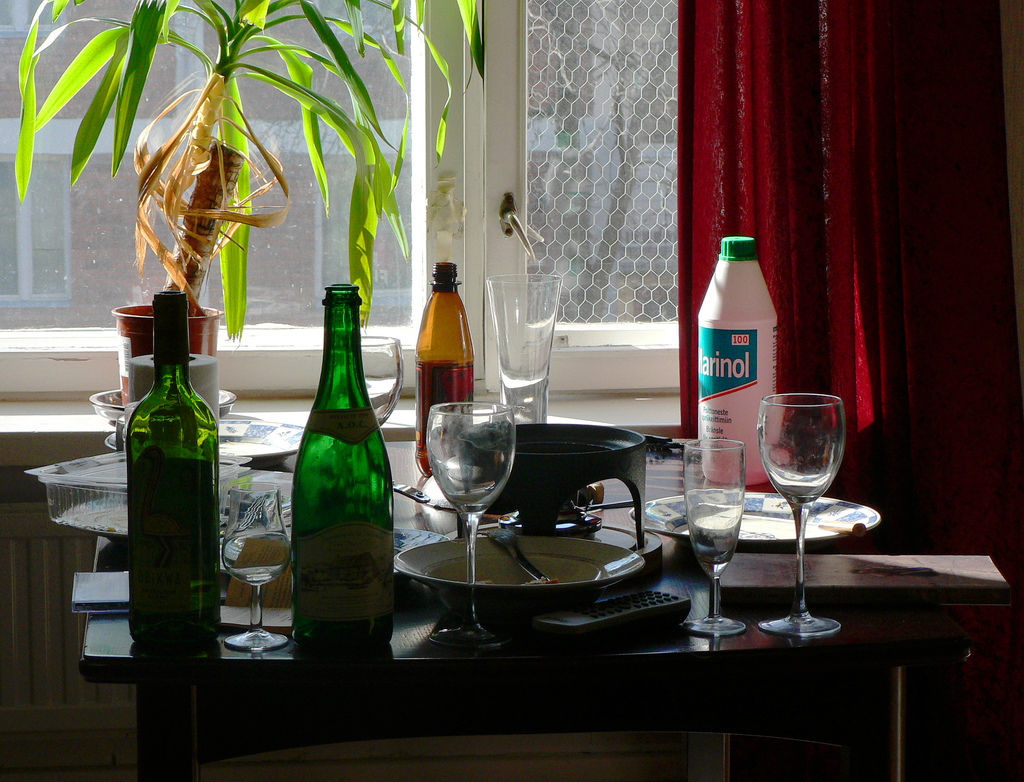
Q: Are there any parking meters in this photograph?
A: No, there are no parking meters.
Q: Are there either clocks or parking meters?
A: No, there are no parking meters or clocks.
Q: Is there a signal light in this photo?
A: No, there are no traffic lights.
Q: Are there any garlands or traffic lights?
A: No, there are no traffic lights or garlands.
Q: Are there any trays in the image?
A: No, there are no trays.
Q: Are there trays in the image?
A: No, there are no trays.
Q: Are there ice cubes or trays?
A: No, there are no trays or ice cubes.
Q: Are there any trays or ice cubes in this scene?
A: No, there are no trays or ice cubes.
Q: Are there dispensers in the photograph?
A: No, there are no dispensers.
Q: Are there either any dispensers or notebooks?
A: No, there are no dispensers or notebooks.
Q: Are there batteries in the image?
A: No, there are no batteries.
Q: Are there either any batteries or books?
A: No, there are no batteries or books.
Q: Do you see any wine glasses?
A: Yes, there is a wine glass.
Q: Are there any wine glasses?
A: Yes, there is a wine glass.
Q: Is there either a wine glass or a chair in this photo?
A: Yes, there is a wine glass.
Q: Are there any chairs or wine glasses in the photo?
A: Yes, there is a wine glass.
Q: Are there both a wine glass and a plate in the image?
A: Yes, there are both a wine glass and a plate.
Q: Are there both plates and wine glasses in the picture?
A: Yes, there are both a wine glass and a plate.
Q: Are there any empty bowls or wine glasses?
A: Yes, there is an empty wine glass.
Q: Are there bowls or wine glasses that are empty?
A: Yes, the wine glass is empty.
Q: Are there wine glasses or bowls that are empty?
A: Yes, the wine glass is empty.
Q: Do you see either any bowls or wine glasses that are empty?
A: Yes, the wine glass is empty.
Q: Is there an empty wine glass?
A: Yes, there is an empty wine glass.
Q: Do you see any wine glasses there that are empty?
A: Yes, there is a wine glass that is empty.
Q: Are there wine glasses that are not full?
A: Yes, there is a empty wine glass.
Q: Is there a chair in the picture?
A: No, there are no chairs.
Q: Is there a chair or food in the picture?
A: No, there are no chairs or food.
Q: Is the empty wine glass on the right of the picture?
A: Yes, the wineglass is on the right of the image.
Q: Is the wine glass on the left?
A: No, the wine glass is on the right of the image.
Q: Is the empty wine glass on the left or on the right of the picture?
A: The wine glass is on the right of the image.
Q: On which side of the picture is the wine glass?
A: The wine glass is on the right of the image.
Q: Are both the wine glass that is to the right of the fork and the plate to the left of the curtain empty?
A: Yes, both the wine glass and the plate are empty.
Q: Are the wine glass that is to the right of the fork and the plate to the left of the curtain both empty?
A: Yes, both the wine glass and the plate are empty.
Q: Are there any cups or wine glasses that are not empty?
A: No, there is a wine glass but it is empty.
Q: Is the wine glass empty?
A: Yes, the wine glass is empty.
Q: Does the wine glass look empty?
A: Yes, the wine glass is empty.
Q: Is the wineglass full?
A: No, the wineglass is empty.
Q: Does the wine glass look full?
A: No, the wine glass is empty.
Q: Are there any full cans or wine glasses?
A: No, there is a wine glass but it is empty.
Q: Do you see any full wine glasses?
A: No, there is a wine glass but it is empty.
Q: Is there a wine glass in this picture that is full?
A: No, there is a wine glass but it is empty.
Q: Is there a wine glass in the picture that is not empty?
A: No, there is a wine glass but it is empty.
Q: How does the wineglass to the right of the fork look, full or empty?
A: The wineglass is empty.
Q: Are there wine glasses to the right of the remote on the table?
A: Yes, there is a wine glass to the right of the remote control.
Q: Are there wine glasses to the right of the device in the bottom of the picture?
A: Yes, there is a wine glass to the right of the remote control.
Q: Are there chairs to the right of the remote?
A: No, there is a wine glass to the right of the remote.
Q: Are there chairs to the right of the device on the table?
A: No, there is a wine glass to the right of the remote.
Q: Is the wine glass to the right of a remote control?
A: Yes, the wine glass is to the right of a remote control.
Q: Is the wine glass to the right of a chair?
A: No, the wine glass is to the right of a remote control.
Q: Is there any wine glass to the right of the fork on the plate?
A: Yes, there is a wine glass to the right of the fork.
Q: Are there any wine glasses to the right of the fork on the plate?
A: Yes, there is a wine glass to the right of the fork.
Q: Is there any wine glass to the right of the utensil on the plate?
A: Yes, there is a wine glass to the right of the fork.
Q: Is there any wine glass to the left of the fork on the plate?
A: No, the wine glass is to the right of the fork.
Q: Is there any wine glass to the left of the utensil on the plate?
A: No, the wine glass is to the right of the fork.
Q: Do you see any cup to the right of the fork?
A: No, there is a wine glass to the right of the fork.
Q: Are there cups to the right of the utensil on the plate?
A: No, there is a wine glass to the right of the fork.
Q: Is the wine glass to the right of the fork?
A: Yes, the wine glass is to the right of the fork.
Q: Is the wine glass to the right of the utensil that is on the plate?
A: Yes, the wine glass is to the right of the fork.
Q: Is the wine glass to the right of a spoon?
A: No, the wine glass is to the right of the fork.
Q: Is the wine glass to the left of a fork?
A: No, the wine glass is to the right of a fork.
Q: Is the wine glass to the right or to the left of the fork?
A: The wine glass is to the right of the fork.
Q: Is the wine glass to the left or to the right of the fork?
A: The wine glass is to the right of the fork.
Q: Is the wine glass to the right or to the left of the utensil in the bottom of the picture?
A: The wine glass is to the right of the fork.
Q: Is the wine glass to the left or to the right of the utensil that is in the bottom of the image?
A: The wine glass is to the right of the fork.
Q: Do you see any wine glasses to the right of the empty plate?
A: Yes, there is a wine glass to the right of the plate.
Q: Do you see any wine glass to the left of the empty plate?
A: No, the wine glass is to the right of the plate.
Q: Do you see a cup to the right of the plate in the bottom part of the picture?
A: No, there is a wine glass to the right of the plate.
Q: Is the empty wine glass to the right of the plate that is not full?
A: Yes, the wine glass is to the right of the plate.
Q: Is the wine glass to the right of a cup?
A: No, the wine glass is to the right of the plate.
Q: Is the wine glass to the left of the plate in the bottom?
A: No, the wine glass is to the right of the plate.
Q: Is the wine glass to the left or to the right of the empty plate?
A: The wine glass is to the right of the plate.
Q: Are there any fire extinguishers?
A: No, there are no fire extinguishers.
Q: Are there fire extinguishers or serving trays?
A: No, there are no fire extinguishers or serving trays.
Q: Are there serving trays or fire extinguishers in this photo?
A: No, there are no fire extinguishers or serving trays.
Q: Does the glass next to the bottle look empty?
A: Yes, the glass is empty.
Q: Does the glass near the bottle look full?
A: No, the glass is empty.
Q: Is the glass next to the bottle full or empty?
A: The glass is empty.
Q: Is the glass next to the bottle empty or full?
A: The glass is empty.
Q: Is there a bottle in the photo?
A: Yes, there is a bottle.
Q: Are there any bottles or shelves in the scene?
A: Yes, there is a bottle.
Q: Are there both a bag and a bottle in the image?
A: No, there is a bottle but no bags.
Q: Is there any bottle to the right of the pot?
A: Yes, there is a bottle to the right of the pot.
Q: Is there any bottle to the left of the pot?
A: No, the bottle is to the right of the pot.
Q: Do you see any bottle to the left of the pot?
A: No, the bottle is to the right of the pot.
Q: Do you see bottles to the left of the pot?
A: No, the bottle is to the right of the pot.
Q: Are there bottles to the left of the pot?
A: No, the bottle is to the right of the pot.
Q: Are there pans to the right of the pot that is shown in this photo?
A: No, there is a bottle to the right of the pot.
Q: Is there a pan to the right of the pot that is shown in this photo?
A: No, there is a bottle to the right of the pot.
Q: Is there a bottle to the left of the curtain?
A: Yes, there is a bottle to the left of the curtain.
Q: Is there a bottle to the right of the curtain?
A: No, the bottle is to the left of the curtain.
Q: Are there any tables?
A: Yes, there is a table.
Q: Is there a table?
A: Yes, there is a table.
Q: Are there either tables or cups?
A: Yes, there is a table.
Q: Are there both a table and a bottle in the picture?
A: Yes, there are both a table and a bottle.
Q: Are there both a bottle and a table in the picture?
A: Yes, there are both a table and a bottle.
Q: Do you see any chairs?
A: No, there are no chairs.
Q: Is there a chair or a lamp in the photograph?
A: No, there are no chairs or lamps.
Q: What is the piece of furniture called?
A: The piece of furniture is a table.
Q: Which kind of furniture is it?
A: The piece of furniture is a table.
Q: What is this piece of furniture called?
A: That is a table.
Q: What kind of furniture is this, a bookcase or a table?
A: That is a table.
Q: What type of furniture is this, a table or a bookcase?
A: That is a table.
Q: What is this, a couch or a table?
A: This is a table.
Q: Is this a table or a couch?
A: This is a table.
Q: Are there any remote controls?
A: Yes, there is a remote control.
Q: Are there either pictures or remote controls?
A: Yes, there is a remote control.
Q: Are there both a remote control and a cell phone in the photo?
A: No, there is a remote control but no cell phones.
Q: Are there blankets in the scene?
A: No, there are no blankets.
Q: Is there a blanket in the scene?
A: No, there are no blankets.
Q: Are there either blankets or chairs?
A: No, there are no blankets or chairs.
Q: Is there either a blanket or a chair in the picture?
A: No, there are no blankets or chairs.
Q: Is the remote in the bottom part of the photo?
A: Yes, the remote is in the bottom of the image.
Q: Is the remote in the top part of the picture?
A: No, the remote is in the bottom of the image.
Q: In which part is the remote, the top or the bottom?
A: The remote is in the bottom of the image.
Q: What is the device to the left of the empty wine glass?
A: The device is a remote control.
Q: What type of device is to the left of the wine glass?
A: The device is a remote control.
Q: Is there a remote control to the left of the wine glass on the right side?
A: Yes, there is a remote control to the left of the wineglass.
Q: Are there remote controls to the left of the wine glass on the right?
A: Yes, there is a remote control to the left of the wineglass.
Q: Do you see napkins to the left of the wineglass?
A: No, there is a remote control to the left of the wineglass.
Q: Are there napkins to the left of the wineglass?
A: No, there is a remote control to the left of the wineglass.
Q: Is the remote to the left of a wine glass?
A: Yes, the remote is to the left of a wine glass.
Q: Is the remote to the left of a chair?
A: No, the remote is to the left of a wine glass.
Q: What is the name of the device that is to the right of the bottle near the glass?
A: The device is a remote control.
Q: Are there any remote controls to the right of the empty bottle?
A: Yes, there is a remote control to the right of the bottle.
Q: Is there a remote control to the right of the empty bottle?
A: Yes, there is a remote control to the right of the bottle.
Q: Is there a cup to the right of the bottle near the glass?
A: No, there is a remote control to the right of the bottle.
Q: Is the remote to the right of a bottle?
A: Yes, the remote is to the right of a bottle.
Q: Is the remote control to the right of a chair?
A: No, the remote control is to the right of a bottle.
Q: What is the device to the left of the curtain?
A: The device is a remote control.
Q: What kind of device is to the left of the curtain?
A: The device is a remote control.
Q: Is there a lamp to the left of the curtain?
A: No, there is a remote control to the left of the curtain.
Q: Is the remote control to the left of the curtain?
A: Yes, the remote control is to the left of the curtain.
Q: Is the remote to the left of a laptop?
A: No, the remote is to the left of the curtain.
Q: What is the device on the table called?
A: The device is a remote control.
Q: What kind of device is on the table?
A: The device is a remote control.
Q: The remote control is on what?
A: The remote control is on the table.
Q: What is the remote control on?
A: The remote control is on the table.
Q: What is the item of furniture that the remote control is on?
A: The piece of furniture is a table.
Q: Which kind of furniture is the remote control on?
A: The remote control is on the table.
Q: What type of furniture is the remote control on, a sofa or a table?
A: The remote control is on a table.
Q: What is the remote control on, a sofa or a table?
A: The remote control is on a table.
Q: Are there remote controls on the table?
A: Yes, there is a remote control on the table.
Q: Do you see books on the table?
A: No, there is a remote control on the table.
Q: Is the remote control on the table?
A: Yes, the remote control is on the table.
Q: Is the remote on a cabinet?
A: No, the remote is on the table.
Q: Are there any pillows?
A: No, there are no pillows.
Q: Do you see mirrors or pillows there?
A: No, there are no pillows or mirrors.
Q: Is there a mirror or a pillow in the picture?
A: No, there are no pillows or mirrors.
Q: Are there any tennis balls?
A: No, there are no tennis balls.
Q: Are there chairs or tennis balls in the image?
A: No, there are no tennis balls or chairs.